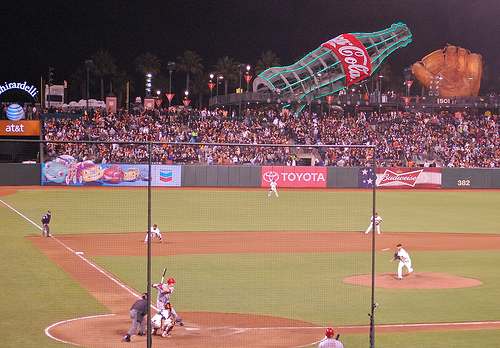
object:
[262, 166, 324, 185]
toyota sign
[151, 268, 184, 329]
batter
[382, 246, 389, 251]
ball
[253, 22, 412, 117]
coke bottle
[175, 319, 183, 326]
catcher's mitt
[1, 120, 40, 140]
sign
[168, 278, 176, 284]
helmet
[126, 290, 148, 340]
umpire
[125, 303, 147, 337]
uniform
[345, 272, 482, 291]
mound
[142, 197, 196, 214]
grass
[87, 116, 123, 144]
fans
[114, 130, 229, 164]
stands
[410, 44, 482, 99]
baseball glove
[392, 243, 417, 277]
pitcher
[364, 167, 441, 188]
budweiser sign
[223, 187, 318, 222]
outfield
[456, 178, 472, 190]
numbers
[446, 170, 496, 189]
fence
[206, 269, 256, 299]
field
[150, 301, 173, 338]
catcher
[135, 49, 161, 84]
palm tree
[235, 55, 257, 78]
light fixture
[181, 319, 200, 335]
home plate